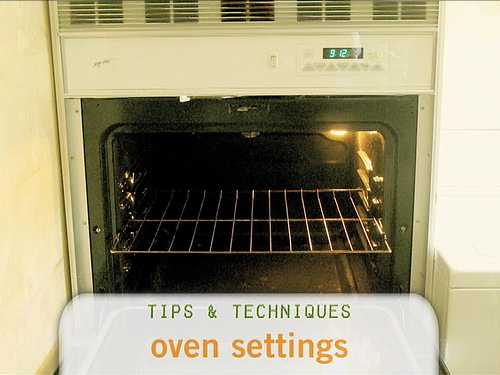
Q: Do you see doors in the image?
A: Yes, there is a door.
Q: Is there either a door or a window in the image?
A: Yes, there is a door.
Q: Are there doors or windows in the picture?
A: Yes, there is a door.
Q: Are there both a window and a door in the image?
A: No, there is a door but no windows.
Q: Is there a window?
A: No, there are no windows.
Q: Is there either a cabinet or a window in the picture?
A: No, there are no windows or cabinets.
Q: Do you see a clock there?
A: Yes, there is a clock.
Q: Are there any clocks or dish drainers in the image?
A: Yes, there is a clock.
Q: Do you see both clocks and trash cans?
A: No, there is a clock but no trash cans.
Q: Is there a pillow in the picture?
A: No, there are no pillows.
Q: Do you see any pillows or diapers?
A: No, there are no pillows or diapers.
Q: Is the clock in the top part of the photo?
A: Yes, the clock is in the top of the image.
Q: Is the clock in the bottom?
A: No, the clock is in the top of the image.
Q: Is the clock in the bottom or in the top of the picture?
A: The clock is in the top of the image.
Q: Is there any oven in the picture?
A: Yes, there is an oven.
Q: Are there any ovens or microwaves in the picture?
A: Yes, there is an oven.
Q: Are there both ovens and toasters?
A: No, there is an oven but no toasters.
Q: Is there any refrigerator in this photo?
A: No, there are no refrigerators.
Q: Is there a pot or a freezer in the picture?
A: No, there are no refrigerators or pots.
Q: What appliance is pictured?
A: The appliance is an oven.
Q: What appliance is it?
A: The appliance is an oven.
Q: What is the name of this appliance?
A: This is an oven.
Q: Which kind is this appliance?
A: This is an oven.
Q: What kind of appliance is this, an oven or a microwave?
A: This is an oven.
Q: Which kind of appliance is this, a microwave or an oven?
A: This is an oven.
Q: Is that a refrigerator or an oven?
A: That is an oven.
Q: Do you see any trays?
A: No, there are no trays.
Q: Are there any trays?
A: No, there are no trays.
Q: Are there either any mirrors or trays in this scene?
A: No, there are no trays or mirrors.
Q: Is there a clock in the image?
A: Yes, there is a clock.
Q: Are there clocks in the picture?
A: Yes, there is a clock.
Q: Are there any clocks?
A: Yes, there is a clock.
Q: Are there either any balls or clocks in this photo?
A: Yes, there is a clock.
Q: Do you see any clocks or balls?
A: Yes, there is a clock.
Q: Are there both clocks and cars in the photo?
A: No, there is a clock but no cars.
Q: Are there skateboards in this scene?
A: No, there are no skateboards.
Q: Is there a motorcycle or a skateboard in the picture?
A: No, there are no skateboards or motorcycles.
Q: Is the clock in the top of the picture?
A: Yes, the clock is in the top of the image.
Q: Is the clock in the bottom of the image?
A: No, the clock is in the top of the image.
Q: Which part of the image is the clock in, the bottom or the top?
A: The clock is in the top of the image.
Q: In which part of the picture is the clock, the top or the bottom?
A: The clock is in the top of the image.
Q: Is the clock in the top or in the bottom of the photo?
A: The clock is in the top of the image.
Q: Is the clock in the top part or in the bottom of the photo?
A: The clock is in the top of the image.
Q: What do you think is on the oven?
A: The clock is on the oven.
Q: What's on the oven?
A: The clock is on the oven.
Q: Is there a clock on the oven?
A: Yes, there is a clock on the oven.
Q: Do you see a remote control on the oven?
A: No, there is a clock on the oven.